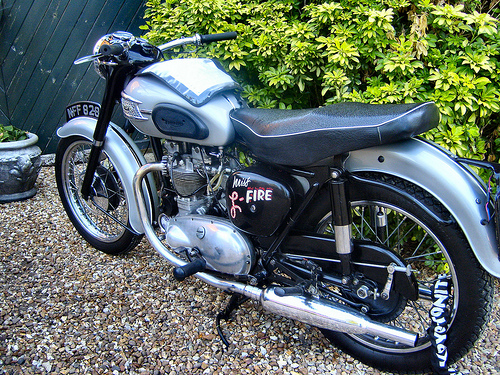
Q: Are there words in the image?
A: Yes, there are words.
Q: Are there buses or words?
A: Yes, there are words.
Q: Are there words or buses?
A: Yes, there are words.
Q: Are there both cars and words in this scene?
A: No, there are words but no cars.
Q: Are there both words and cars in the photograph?
A: No, there are words but no cars.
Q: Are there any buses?
A: No, there are no buses.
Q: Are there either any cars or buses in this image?
A: No, there are no buses or cars.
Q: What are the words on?
A: The words are on the motorbike.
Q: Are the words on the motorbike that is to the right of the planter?
A: Yes, the words are on the motorcycle.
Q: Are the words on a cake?
A: No, the words are on the motorcycle.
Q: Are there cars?
A: No, there are no cars.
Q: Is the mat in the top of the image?
A: Yes, the mat is in the top of the image.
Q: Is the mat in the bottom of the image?
A: No, the mat is in the top of the image.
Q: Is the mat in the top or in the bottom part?
A: The mat is in the top of the image.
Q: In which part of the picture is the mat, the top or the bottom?
A: The mat is in the top of the image.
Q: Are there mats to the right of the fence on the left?
A: Yes, there is a mat to the right of the fence.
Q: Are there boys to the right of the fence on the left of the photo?
A: No, there is a mat to the right of the fence.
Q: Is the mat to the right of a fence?
A: Yes, the mat is to the right of a fence.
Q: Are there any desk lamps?
A: No, there are no desk lamps.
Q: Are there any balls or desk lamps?
A: No, there are no desk lamps or balls.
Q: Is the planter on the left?
A: Yes, the planter is on the left of the image.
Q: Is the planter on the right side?
A: No, the planter is on the left of the image.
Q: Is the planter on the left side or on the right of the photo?
A: The planter is on the left of the image.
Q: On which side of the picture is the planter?
A: The planter is on the left of the image.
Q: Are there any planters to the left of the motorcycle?
A: Yes, there is a planter to the left of the motorcycle.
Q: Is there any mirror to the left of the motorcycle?
A: No, there is a planter to the left of the motorcycle.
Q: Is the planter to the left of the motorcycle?
A: Yes, the planter is to the left of the motorcycle.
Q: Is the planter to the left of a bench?
A: No, the planter is to the left of the motorcycle.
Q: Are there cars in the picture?
A: No, there are no cars.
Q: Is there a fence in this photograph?
A: Yes, there is a fence.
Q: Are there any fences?
A: Yes, there is a fence.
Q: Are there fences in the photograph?
A: Yes, there is a fence.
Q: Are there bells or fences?
A: Yes, there is a fence.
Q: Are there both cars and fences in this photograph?
A: No, there is a fence but no cars.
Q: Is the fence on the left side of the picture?
A: Yes, the fence is on the left of the image.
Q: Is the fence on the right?
A: No, the fence is on the left of the image.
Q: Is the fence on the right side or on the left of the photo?
A: The fence is on the left of the image.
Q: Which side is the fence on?
A: The fence is on the left of the image.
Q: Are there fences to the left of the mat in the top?
A: Yes, there is a fence to the left of the mat.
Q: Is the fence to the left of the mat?
A: Yes, the fence is to the left of the mat.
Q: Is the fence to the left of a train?
A: No, the fence is to the left of the mat.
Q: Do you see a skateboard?
A: No, there are no skateboards.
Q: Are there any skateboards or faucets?
A: No, there are no skateboards or faucets.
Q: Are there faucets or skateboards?
A: No, there are no skateboards or faucets.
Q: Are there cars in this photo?
A: No, there are no cars.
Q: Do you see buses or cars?
A: No, there are no cars or buses.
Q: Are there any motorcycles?
A: Yes, there is a motorcycle.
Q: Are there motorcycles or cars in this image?
A: Yes, there is a motorcycle.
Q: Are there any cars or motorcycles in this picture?
A: Yes, there is a motorcycle.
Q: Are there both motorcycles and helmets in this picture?
A: No, there is a motorcycle but no helmets.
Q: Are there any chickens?
A: No, there are no chickens.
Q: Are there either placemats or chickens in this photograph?
A: No, there are no chickens or placemats.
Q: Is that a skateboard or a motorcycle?
A: That is a motorcycle.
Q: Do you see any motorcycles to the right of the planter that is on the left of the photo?
A: Yes, there is a motorcycle to the right of the planter.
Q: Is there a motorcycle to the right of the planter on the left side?
A: Yes, there is a motorcycle to the right of the planter.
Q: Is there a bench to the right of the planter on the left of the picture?
A: No, there is a motorcycle to the right of the planter.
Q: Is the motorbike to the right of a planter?
A: Yes, the motorbike is to the right of a planter.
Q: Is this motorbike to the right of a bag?
A: No, the motorbike is to the right of a planter.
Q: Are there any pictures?
A: No, there are no pictures.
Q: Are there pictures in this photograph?
A: No, there are no pictures.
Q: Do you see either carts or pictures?
A: No, there are no pictures or carts.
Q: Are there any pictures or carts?
A: No, there are no pictures or carts.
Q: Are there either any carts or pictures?
A: No, there are no pictures or carts.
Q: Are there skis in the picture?
A: No, there are no skis.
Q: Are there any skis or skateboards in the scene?
A: No, there are no skis or skateboards.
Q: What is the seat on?
A: The seat is on the motorbike.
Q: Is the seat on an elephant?
A: No, the seat is on the motorbike.